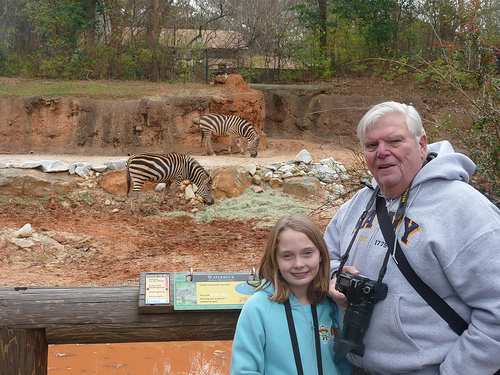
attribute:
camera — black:
[334, 182, 409, 359]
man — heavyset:
[325, 101, 500, 374]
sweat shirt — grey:
[321, 140, 497, 375]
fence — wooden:
[2, 284, 269, 375]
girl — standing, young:
[232, 218, 344, 375]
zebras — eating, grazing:
[124, 112, 262, 215]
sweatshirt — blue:
[230, 285, 349, 375]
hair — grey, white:
[354, 98, 427, 144]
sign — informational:
[139, 266, 261, 315]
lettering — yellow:
[345, 205, 421, 250]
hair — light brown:
[251, 213, 332, 308]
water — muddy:
[5, 211, 238, 374]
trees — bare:
[95, 2, 310, 85]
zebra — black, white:
[122, 147, 215, 212]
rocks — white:
[222, 139, 344, 187]